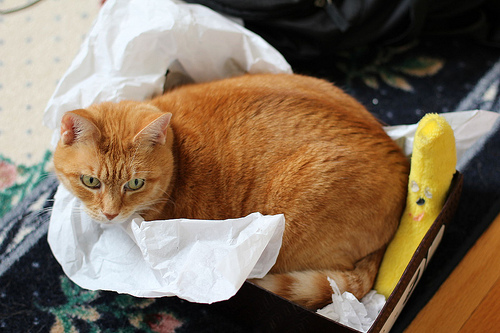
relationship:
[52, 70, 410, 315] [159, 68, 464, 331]
cat in box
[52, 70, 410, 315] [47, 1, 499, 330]
cat on tissue paper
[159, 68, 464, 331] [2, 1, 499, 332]
box on carpet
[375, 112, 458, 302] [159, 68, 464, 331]
toy in box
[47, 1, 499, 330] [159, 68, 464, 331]
tissue paper in box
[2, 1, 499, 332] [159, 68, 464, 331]
carpet under box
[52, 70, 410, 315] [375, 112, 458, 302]
cat has toy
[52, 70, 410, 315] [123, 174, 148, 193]
cat has eye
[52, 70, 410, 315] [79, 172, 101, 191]
cat has eye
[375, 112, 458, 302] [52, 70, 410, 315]
toy next to cat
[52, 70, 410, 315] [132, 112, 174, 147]
cat has ear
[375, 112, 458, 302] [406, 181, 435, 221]
toy has face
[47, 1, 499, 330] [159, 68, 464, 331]
tissue paper lining box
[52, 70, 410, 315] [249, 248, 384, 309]
cat has tail